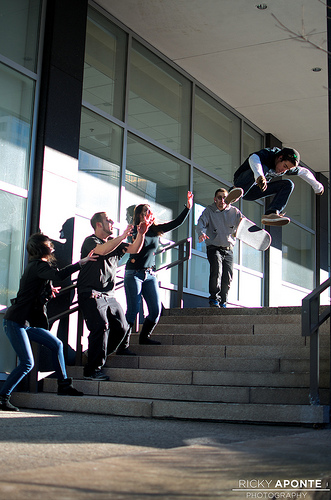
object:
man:
[196, 187, 241, 307]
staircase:
[19, 394, 321, 423]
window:
[128, 37, 192, 159]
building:
[0, 0, 331, 309]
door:
[282, 220, 315, 307]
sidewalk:
[0, 418, 331, 500]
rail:
[47, 238, 191, 321]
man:
[224, 146, 323, 225]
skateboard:
[236, 217, 271, 251]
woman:
[118, 189, 194, 355]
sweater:
[125, 207, 190, 270]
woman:
[0, 233, 97, 413]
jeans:
[0, 320, 67, 398]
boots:
[58, 377, 83, 396]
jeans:
[124, 269, 162, 323]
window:
[0, 54, 36, 199]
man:
[78, 213, 152, 381]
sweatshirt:
[196, 203, 245, 248]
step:
[42, 378, 309, 403]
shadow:
[0, 417, 331, 448]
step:
[163, 308, 301, 315]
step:
[155, 324, 303, 334]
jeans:
[79, 292, 130, 372]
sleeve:
[249, 154, 265, 180]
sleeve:
[298, 167, 324, 195]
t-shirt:
[234, 147, 323, 194]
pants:
[206, 245, 233, 300]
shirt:
[78, 236, 128, 298]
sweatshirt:
[5, 260, 83, 325]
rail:
[302, 279, 331, 337]